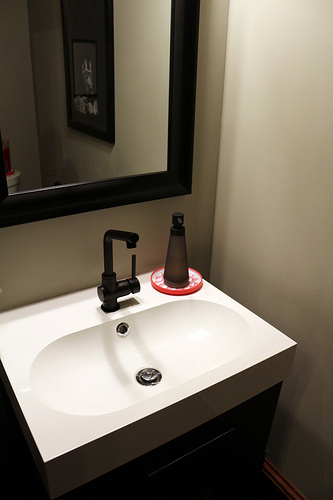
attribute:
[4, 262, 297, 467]
sink — white, square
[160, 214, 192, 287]
soap pump — brown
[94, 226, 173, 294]
faucet — black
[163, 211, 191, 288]
soap dispenser — brown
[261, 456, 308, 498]
trim — wood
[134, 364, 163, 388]
drain — chrome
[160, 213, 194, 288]
soap dispenser — black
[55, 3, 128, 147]
picture — large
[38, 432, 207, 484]
sink — brown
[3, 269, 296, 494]
sink — white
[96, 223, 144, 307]
faucet — black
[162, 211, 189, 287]
bottle — black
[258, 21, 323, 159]
walls — white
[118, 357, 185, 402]
hole — small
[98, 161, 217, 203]
rim — black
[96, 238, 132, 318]
pipe — black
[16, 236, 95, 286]
paint — tan